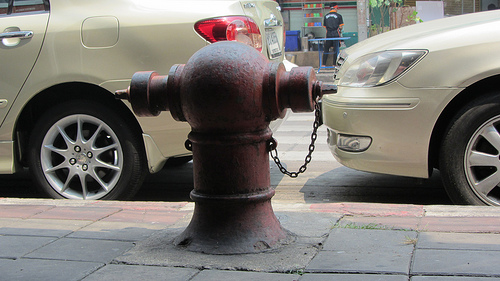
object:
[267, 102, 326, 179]
chain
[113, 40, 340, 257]
hydrant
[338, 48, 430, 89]
headlight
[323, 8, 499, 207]
car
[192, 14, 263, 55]
taillight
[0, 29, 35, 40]
handle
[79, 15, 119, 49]
tank door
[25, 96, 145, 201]
tire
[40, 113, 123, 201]
wheel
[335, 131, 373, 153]
light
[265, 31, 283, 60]
plate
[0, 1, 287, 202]
car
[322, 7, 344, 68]
man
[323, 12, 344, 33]
shirt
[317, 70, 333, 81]
block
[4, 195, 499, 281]
sidewalk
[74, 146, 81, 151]
nuts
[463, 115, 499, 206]
wheel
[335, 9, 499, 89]
hood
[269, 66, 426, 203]
street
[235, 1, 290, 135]
rear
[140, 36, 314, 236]
weathered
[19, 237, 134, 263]
individual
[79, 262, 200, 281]
stone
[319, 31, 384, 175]
head